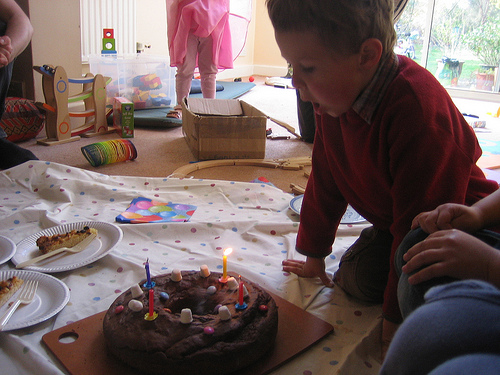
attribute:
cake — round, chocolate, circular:
[102, 268, 278, 373]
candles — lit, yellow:
[137, 247, 249, 314]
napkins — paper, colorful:
[119, 192, 196, 231]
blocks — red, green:
[97, 28, 118, 56]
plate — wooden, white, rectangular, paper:
[34, 268, 336, 374]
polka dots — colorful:
[1, 160, 398, 374]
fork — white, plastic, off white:
[24, 235, 96, 268]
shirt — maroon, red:
[293, 53, 482, 319]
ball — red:
[247, 75, 258, 84]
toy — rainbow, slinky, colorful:
[77, 136, 139, 167]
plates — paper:
[2, 219, 124, 335]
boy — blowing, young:
[260, 1, 498, 298]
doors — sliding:
[389, 2, 498, 104]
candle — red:
[148, 285, 157, 318]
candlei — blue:
[141, 261, 157, 284]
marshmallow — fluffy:
[179, 305, 191, 322]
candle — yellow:
[220, 255, 234, 283]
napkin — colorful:
[118, 193, 197, 231]